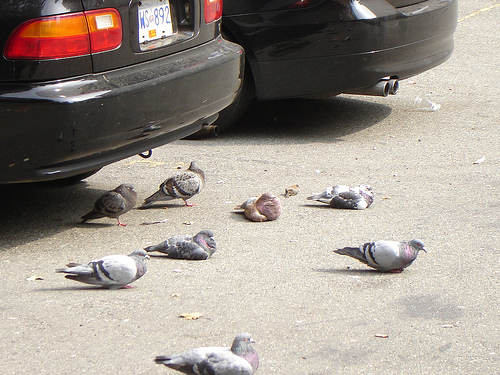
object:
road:
[2, 0, 499, 375]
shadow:
[173, 95, 394, 149]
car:
[210, 0, 459, 137]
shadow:
[0, 180, 114, 254]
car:
[1, 0, 247, 188]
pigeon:
[76, 180, 140, 229]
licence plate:
[136, 0, 174, 46]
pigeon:
[302, 182, 376, 213]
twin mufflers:
[340, 76, 391, 97]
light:
[203, 0, 223, 24]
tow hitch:
[136, 148, 155, 159]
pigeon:
[54, 244, 153, 292]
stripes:
[92, 260, 115, 283]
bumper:
[225, 0, 461, 103]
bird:
[232, 190, 285, 223]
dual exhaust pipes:
[342, 78, 401, 97]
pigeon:
[331, 235, 431, 278]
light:
[1, 7, 125, 62]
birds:
[137, 158, 205, 210]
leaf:
[284, 184, 302, 199]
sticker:
[147, 29, 159, 37]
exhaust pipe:
[180, 124, 220, 140]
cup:
[411, 94, 442, 113]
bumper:
[1, 32, 244, 187]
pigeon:
[141, 229, 220, 263]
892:
[153, 6, 170, 27]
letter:
[138, 10, 146, 30]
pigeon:
[152, 331, 262, 375]